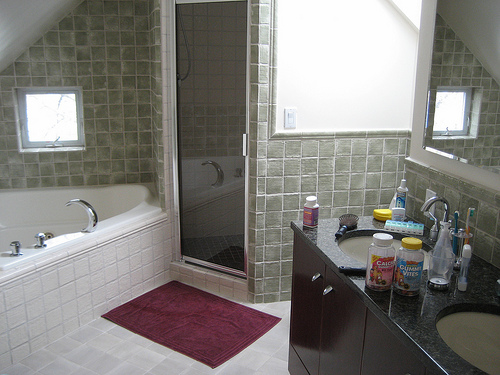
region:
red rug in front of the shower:
[100, 280, 280, 368]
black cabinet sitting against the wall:
[286, 212, 496, 372]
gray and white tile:
[0, 0, 410, 305]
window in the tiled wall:
[11, 83, 84, 150]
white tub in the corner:
[0, 183, 171, 358]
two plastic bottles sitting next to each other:
[364, 232, 424, 294]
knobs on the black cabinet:
[310, 270, 335, 295]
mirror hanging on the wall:
[421, 2, 496, 184]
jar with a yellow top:
[395, 235, 422, 312]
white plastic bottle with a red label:
[302, 197, 319, 232]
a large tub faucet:
[58, 190, 108, 232]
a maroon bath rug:
[98, 274, 285, 369]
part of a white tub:
[1, 175, 151, 257]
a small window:
[16, 86, 85, 146]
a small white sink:
[343, 227, 437, 267]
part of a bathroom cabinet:
[283, 241, 434, 373]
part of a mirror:
[406, 0, 498, 185]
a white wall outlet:
[283, 105, 300, 131]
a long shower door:
[167, 0, 247, 280]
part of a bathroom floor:
[14, 321, 209, 373]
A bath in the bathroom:
[0, 180, 157, 281]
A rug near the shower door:
[101, 282, 282, 368]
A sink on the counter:
[339, 194, 455, 264]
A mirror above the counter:
[421, 1, 499, 171]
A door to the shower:
[180, 4, 250, 274]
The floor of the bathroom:
[0, 281, 290, 374]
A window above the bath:
[20, 92, 80, 147]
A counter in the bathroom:
[290, 214, 499, 372]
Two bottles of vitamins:
[364, 234, 424, 294]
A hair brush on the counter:
[335, 215, 360, 239]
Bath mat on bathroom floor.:
[99, 271, 284, 374]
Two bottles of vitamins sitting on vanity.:
[363, 229, 428, 304]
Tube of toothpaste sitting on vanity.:
[391, 176, 412, 208]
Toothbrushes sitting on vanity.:
[451, 204, 480, 243]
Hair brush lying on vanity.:
[330, 207, 362, 241]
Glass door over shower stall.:
[168, 4, 257, 280]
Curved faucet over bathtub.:
[57, 189, 104, 236]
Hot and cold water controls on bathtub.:
[8, 231, 52, 263]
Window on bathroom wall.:
[5, 79, 97, 156]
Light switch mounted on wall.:
[280, 102, 302, 133]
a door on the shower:
[171, 7, 248, 260]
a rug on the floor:
[102, 272, 268, 354]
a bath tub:
[2, 190, 132, 235]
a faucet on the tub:
[61, 195, 103, 225]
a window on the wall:
[21, 90, 81, 145]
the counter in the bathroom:
[301, 203, 495, 348]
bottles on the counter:
[362, 233, 444, 284]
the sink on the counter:
[430, 310, 496, 357]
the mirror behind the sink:
[426, 30, 498, 165]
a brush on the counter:
[331, 207, 356, 237]